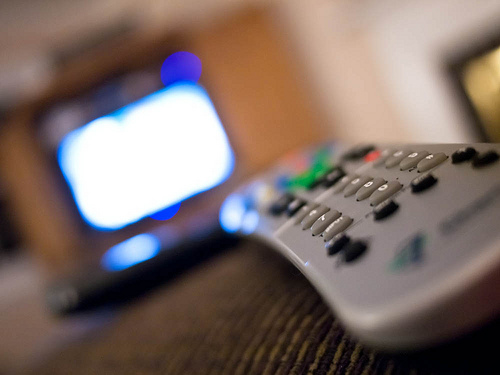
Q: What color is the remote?
A: Gray.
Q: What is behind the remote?
A: A television.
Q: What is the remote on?
A: A cushion.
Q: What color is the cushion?
A: Brown and tan.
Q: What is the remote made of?
A: Plastic.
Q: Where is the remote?
A: On the cushion.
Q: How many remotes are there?
A: One.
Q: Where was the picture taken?
A: In a living room.